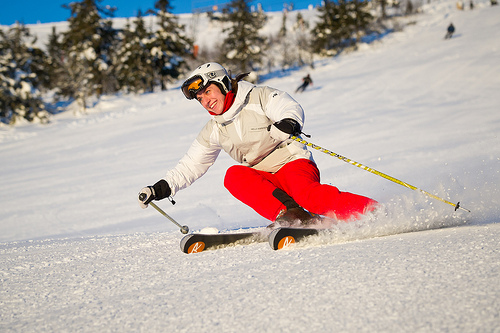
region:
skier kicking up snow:
[125, 58, 468, 258]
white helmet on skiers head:
[170, 55, 235, 115]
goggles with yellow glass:
[175, 67, 210, 97]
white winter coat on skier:
[160, 61, 310, 196]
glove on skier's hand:
[255, 112, 306, 153]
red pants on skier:
[210, 156, 380, 233]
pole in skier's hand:
[271, 126, 474, 224]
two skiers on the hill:
[286, 19, 464, 101]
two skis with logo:
[165, 225, 326, 249]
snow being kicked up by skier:
[366, 179, 481, 244]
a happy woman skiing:
[130, 59, 475, 260]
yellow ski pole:
[265, 116, 478, 221]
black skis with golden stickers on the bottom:
[167, 221, 342, 253]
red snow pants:
[218, 159, 388, 226]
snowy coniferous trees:
[1, 2, 178, 135]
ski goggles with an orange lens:
[176, 70, 210, 100]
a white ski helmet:
[176, 55, 238, 100]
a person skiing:
[289, 68, 325, 95]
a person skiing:
[438, 18, 461, 44]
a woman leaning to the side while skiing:
[127, 55, 474, 264]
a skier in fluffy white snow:
[78, 77, 412, 271]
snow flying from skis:
[285, 210, 476, 261]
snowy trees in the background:
[35, 22, 147, 144]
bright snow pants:
[215, 165, 371, 248]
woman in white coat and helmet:
[130, 50, 270, 152]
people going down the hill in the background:
[298, 20, 462, 95]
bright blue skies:
[14, 1, 121, 28]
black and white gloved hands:
[125, 179, 190, 219]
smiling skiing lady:
[182, 75, 239, 136]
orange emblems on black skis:
[179, 220, 238, 267]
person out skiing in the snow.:
[82, 40, 468, 251]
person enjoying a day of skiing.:
[77, 45, 478, 279]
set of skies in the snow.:
[137, 204, 429, 271]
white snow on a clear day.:
[44, 255, 427, 305]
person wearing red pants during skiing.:
[129, 64, 388, 231]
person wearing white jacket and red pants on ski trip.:
[82, 56, 468, 275]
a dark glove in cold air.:
[128, 176, 185, 210]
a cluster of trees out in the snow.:
[14, 8, 161, 93]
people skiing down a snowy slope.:
[293, 16, 474, 135]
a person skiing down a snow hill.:
[88, 37, 470, 279]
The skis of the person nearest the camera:
[178, 225, 323, 254]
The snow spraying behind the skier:
[305, 147, 499, 244]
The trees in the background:
[0, 0, 414, 124]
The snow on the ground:
[2, 0, 499, 332]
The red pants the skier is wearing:
[220, 157, 388, 225]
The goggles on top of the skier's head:
[181, 68, 234, 96]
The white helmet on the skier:
[178, 58, 236, 100]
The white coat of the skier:
[158, 86, 319, 191]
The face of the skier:
[196, 84, 224, 117]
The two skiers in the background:
[290, 19, 461, 94]